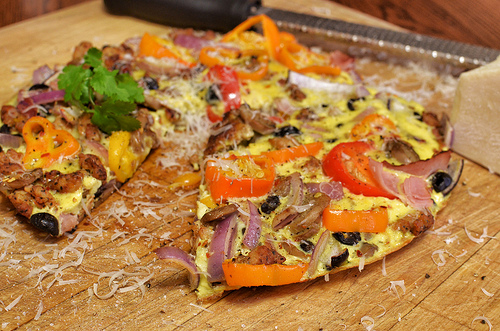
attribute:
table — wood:
[45, 22, 121, 31]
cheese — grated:
[108, 203, 167, 237]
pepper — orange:
[20, 119, 77, 170]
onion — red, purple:
[209, 211, 237, 278]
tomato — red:
[325, 137, 393, 205]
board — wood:
[41, 265, 322, 329]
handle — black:
[124, 0, 259, 35]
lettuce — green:
[87, 95, 141, 123]